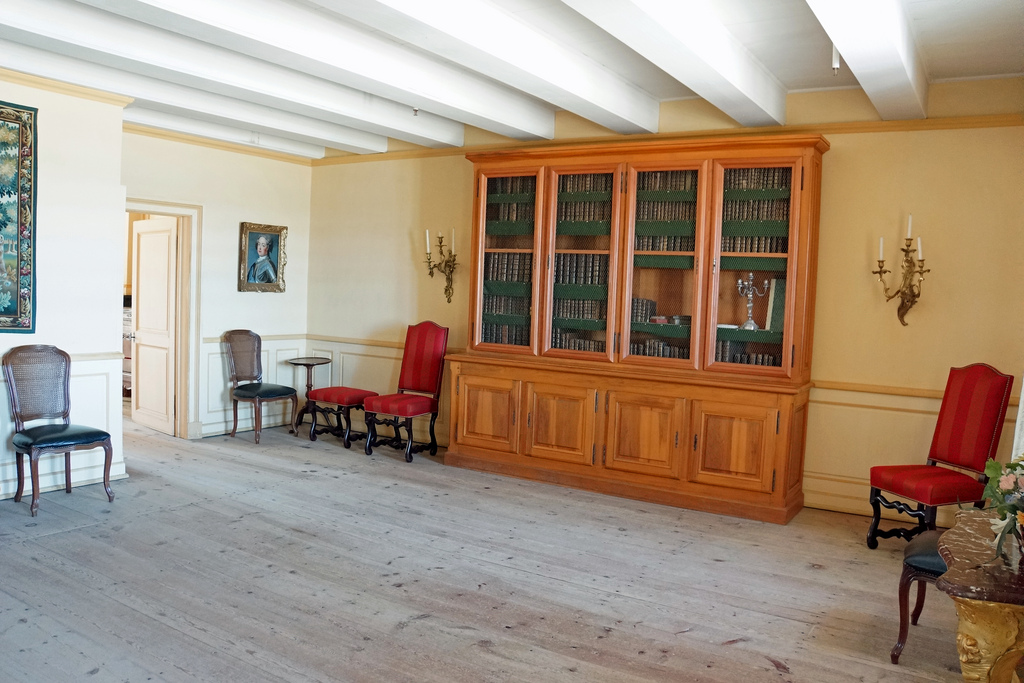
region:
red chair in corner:
[829, 318, 1022, 579]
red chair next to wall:
[339, 291, 454, 462]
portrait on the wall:
[231, 208, 304, 297]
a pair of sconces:
[386, 208, 975, 320]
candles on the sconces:
[860, 199, 937, 282]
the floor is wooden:
[4, 363, 891, 680]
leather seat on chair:
[13, 418, 111, 456]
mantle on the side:
[939, 487, 1022, 639]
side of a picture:
[0, 85, 57, 351]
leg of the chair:
[33, 505, 34, 513]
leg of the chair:
[64, 477, 87, 498]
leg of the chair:
[223, 411, 246, 430]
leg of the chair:
[349, 420, 384, 466]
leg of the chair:
[864, 594, 919, 632]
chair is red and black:
[859, 360, 1015, 561]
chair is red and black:
[361, 317, 456, 463]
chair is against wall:
[1, 344, 128, 515]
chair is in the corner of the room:
[864, 360, 1016, 556]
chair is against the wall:
[365, 315, 460, 459]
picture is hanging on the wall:
[1, 98, 46, 334]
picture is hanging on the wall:
[233, 222, 288, 292]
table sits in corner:
[282, 350, 336, 437]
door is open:
[124, 197, 207, 444]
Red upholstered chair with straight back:
[858, 356, 1015, 557]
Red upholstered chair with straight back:
[359, 318, 454, 474]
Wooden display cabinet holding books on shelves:
[434, 124, 831, 530]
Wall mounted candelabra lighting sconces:
[416, 221, 467, 302]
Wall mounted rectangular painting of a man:
[231, 211, 292, 297]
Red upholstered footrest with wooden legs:
[299, 379, 382, 449]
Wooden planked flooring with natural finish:
[1, 391, 1022, 676]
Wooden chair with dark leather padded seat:
[215, 325, 302, 443]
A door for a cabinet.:
[454, 373, 524, 454]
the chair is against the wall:
[0, 344, 115, 510]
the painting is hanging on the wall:
[234, 218, 293, 296]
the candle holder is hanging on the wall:
[869, 209, 934, 324]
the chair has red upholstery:
[360, 316, 453, 463]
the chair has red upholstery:
[869, 363, 1013, 557]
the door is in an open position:
[124, 201, 195, 437]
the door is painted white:
[128, 210, 179, 427]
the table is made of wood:
[285, 353, 330, 418]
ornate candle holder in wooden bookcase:
[441, 109, 830, 524]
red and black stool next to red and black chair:
[302, 313, 448, 468]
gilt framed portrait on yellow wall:
[123, 128, 314, 443]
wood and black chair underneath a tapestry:
[3, 101, 117, 510]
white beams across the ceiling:
[3, 3, 1022, 159]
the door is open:
[123, 205, 185, 441]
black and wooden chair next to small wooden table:
[213, 318, 332, 442]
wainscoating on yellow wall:
[306, 85, 1022, 520]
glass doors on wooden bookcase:
[441, 133, 827, 522]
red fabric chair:
[858, 337, 1021, 593]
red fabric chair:
[361, 287, 459, 471]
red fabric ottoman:
[298, 372, 366, 443]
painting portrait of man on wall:
[234, 217, 286, 293]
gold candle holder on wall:
[873, 187, 943, 336]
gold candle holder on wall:
[415, 217, 461, 300]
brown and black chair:
[213, 315, 297, 452]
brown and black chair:
[8, 339, 129, 517]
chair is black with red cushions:
[865, 354, 1008, 563]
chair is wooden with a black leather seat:
[2, 344, 117, 515]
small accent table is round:
[289, 350, 332, 430]